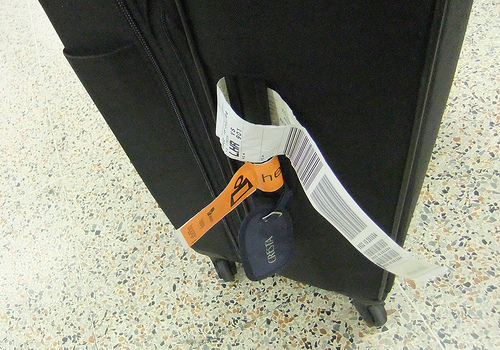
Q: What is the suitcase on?
A: The ground.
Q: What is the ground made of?
A: Tile.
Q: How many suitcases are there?
A: One.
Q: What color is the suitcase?
A: Black.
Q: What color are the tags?
A: Orange, white, and blue.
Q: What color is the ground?
A: White, black, and orange.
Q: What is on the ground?
A: The suitcase.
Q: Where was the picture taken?
A: At an airport.